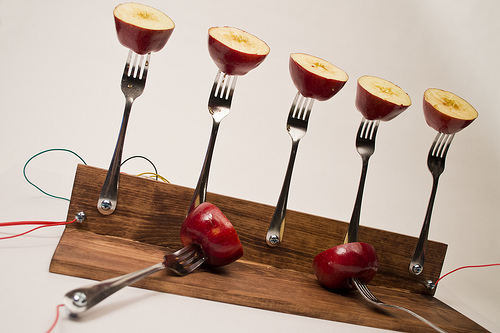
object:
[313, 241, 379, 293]
apple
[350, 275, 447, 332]
fork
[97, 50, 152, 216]
fork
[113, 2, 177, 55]
apple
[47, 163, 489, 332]
wood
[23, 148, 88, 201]
wires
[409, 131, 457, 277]
forks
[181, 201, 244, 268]
apple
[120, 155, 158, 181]
wire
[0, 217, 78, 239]
wire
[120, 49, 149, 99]
tines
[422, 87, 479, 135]
red apples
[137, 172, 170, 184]
wire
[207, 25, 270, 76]
half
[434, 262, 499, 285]
cord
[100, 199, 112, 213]
screw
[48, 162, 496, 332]
board